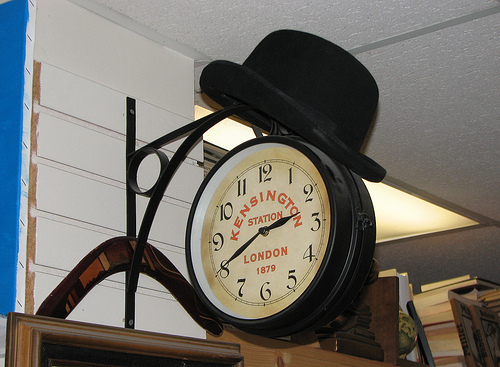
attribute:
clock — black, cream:
[184, 135, 376, 337]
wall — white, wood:
[37, 1, 206, 339]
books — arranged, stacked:
[397, 273, 499, 367]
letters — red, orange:
[230, 190, 301, 275]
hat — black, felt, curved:
[200, 29, 384, 184]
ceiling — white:
[76, 0, 497, 289]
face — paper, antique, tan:
[201, 148, 332, 316]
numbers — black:
[210, 162, 319, 304]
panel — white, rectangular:
[39, 61, 204, 163]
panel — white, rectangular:
[38, 114, 205, 205]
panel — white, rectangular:
[37, 166, 203, 251]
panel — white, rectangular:
[35, 219, 187, 294]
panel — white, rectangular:
[34, 272, 207, 341]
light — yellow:
[196, 107, 477, 243]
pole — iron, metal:
[126, 98, 287, 331]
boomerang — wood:
[38, 238, 225, 335]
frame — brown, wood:
[8, 311, 242, 366]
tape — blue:
[1, 3, 29, 320]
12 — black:
[258, 164, 273, 184]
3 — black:
[312, 212, 321, 231]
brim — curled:
[200, 61, 386, 182]